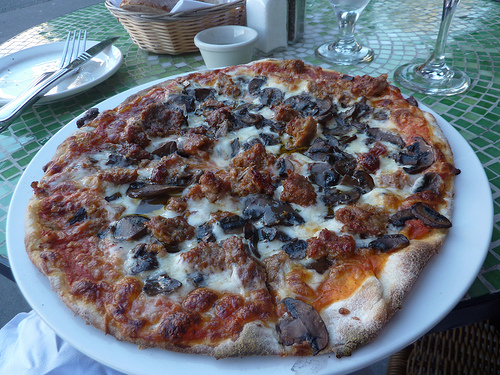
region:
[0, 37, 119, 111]
a small white plate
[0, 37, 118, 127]
a silver knife and fork on a plate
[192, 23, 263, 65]
a small white bowl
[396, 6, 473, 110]
the stem of a wine glass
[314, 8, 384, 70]
a clear glass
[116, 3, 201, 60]
a brown basket with a napkin in it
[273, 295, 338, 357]
a mushroom on a pizza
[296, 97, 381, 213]
several burned mushrooms on a pizza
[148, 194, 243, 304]
melted cheese on a pizza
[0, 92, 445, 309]
a round pizza on a white plate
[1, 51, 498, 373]
pizza on white dish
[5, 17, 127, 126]
fork and knife on dish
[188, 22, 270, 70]
a cup of sauce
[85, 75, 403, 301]
melted cheese on pizza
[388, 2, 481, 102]
the base of a glass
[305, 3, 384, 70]
the base of a glass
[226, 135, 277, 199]
small pieces of meat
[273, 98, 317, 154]
small pieces of meat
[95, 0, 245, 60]
a basket of straw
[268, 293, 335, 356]
slice os mushroom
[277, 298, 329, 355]
A slice of mushroom on a pizza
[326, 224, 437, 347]
The crust on a pizza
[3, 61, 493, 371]
Pizza on a white plate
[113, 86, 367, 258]
A pizza topped with mushrooms and cheese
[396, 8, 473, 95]
Bottom of a wine glass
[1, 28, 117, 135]
A knife and fork in a small plate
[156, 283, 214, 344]
Slightly scorched cheese on a pizza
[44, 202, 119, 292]
Tomato sauce on a pizza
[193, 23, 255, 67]
A small cup for dipping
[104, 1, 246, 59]
A wicker basket of bread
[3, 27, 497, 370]
this is a pizza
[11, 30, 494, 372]
pizza on a plate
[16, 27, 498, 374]
the plate is white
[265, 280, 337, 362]
this is a mushroom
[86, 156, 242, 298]
cheese on the pizza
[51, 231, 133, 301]
red sauce on the pizza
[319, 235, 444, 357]
brown crust on pizza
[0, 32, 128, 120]
knife on a plate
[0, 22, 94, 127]
fork on a plate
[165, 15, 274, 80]
a white glass container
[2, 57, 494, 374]
pizza on round white plate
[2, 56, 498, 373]
round white dinner plate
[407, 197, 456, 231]
slice of mushroom on pizza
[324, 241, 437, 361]
brown blistered section of pizza crust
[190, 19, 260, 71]
white sauce cup near pizza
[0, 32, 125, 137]
silver colored eating utensils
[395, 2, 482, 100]
bottom portion of wine glass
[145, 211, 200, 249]
piece of sausage atop pizza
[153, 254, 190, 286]
section of melted mozzarella cheese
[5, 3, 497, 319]
green mosaic tile table top